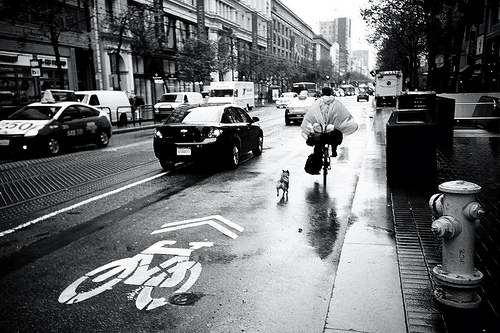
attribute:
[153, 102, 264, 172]
car — black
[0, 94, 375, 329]
street — busy, wet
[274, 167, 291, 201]
dog — running, small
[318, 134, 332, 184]
bicycle — small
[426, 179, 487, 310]
fire hydrant — white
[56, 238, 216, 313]
bicycle — white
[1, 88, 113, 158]
taxi — white, black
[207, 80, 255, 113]
truck — white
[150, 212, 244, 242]
arrows — white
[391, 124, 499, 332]
sidewalk — brick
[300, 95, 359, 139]
raincoat — plastic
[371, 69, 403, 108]
truck — parked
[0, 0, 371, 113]
buildings — in a row